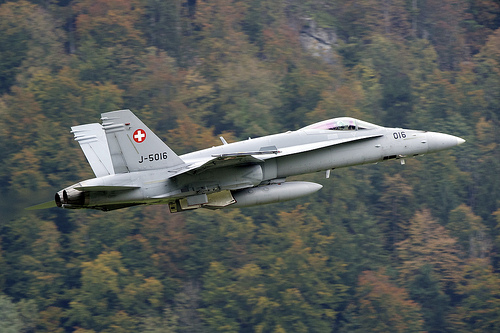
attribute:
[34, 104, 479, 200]
jet — grey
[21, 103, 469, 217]
jet — flying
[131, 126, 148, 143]
logo — red, white, Swiss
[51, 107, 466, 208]
military plane — in flight